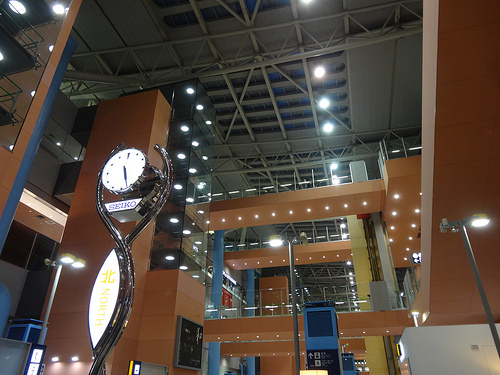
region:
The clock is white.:
[88, 142, 160, 198]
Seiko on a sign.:
[94, 190, 152, 215]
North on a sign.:
[84, 287, 118, 342]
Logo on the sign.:
[88, 259, 133, 294]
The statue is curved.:
[86, 152, 171, 372]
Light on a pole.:
[465, 206, 492, 241]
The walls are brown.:
[143, 286, 168, 350]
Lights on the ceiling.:
[301, 60, 341, 137]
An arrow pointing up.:
[298, 346, 317, 368]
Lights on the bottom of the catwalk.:
[211, 187, 375, 236]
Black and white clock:
[96, 144, 151, 199]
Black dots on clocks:
[131, 144, 148, 164]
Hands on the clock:
[119, 164, 131, 189]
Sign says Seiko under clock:
[97, 196, 146, 212]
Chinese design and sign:
[89, 246, 119, 348]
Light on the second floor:
[258, 224, 295, 259]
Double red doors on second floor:
[220, 287, 235, 309]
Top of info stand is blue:
[302, 302, 338, 349]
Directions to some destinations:
[306, 349, 341, 373]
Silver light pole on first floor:
[438, 204, 498, 365]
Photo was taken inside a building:
[12, 18, 498, 366]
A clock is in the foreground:
[93, 140, 159, 193]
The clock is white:
[93, 146, 155, 198]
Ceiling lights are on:
[299, 1, 338, 146]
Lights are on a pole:
[36, 246, 93, 315]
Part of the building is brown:
[428, 12, 498, 202]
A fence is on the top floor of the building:
[373, 129, 426, 162]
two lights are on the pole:
[38, 252, 95, 282]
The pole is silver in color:
[36, 263, 76, 330]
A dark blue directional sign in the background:
[302, 344, 344, 374]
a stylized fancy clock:
[77, 126, 193, 353]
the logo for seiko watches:
[97, 197, 148, 222]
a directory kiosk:
[306, 302, 325, 374]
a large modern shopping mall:
[30, 38, 486, 360]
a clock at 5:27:
[105, 150, 180, 200]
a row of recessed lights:
[221, 203, 368, 220]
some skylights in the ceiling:
[234, 30, 393, 150]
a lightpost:
[261, 232, 326, 331]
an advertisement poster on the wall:
[176, 314, 191, 373]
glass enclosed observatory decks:
[172, 119, 224, 289]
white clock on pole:
[98, 120, 143, 207]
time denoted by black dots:
[103, 146, 143, 195]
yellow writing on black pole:
[88, 250, 114, 350]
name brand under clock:
[103, 195, 137, 221]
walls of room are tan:
[100, 90, 155, 373]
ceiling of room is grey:
[153, 21, 410, 151]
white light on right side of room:
[446, 209, 488, 239]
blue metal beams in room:
[205, 236, 230, 367]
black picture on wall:
[165, 306, 208, 365]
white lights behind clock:
[59, 251, 83, 280]